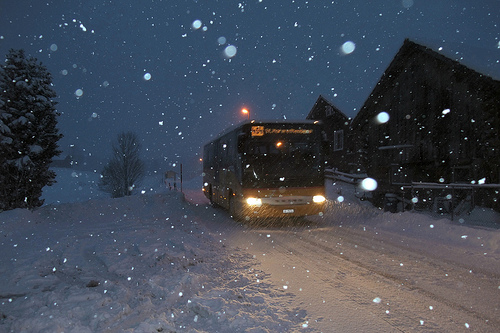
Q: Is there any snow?
A: Yes, there is snow.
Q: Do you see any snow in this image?
A: Yes, there is snow.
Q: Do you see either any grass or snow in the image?
A: Yes, there is snow.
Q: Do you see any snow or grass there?
A: Yes, there is snow.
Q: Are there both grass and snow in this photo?
A: No, there is snow but no grass.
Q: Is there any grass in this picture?
A: No, there is no grass.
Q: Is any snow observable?
A: Yes, there is snow.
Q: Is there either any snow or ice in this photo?
A: Yes, there is snow.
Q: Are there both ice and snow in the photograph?
A: No, there is snow but no ice.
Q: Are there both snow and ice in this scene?
A: No, there is snow but no ice.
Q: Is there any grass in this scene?
A: No, there is no grass.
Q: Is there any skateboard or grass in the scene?
A: No, there are no grass or skateboards.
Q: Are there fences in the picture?
A: No, there are no fences.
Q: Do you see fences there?
A: No, there are no fences.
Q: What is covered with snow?
A: The tree is covered with snow.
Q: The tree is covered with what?
A: The tree is covered with snow.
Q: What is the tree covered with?
A: The tree is covered with snow.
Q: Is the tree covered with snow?
A: Yes, the tree is covered with snow.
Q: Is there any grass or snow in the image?
A: Yes, there is snow.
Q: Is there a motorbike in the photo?
A: No, there are no motorcycles.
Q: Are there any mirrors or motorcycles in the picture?
A: No, there are no motorcycles or mirrors.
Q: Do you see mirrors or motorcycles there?
A: No, there are no motorcycles or mirrors.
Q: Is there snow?
A: Yes, there is snow.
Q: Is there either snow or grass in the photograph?
A: Yes, there is snow.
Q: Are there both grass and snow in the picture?
A: No, there is snow but no grass.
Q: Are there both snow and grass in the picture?
A: No, there is snow but no grass.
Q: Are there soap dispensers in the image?
A: No, there are no soap dispensers.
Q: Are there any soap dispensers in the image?
A: No, there are no soap dispensers.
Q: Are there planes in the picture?
A: No, there are no planes.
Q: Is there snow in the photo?
A: Yes, there is snow.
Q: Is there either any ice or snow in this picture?
A: Yes, there is snow.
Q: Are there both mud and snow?
A: No, there is snow but no mud.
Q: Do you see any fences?
A: No, there are no fences.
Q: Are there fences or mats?
A: No, there are no fences or mats.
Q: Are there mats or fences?
A: No, there are no fences or mats.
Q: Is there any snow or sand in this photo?
A: Yes, there is snow.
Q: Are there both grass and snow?
A: No, there is snow but no grass.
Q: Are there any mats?
A: No, there are no mats.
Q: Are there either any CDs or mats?
A: No, there are no mats or cds.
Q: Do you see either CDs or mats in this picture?
A: No, there are no mats or cds.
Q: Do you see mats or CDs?
A: No, there are no mats or cds.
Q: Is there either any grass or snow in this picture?
A: Yes, there is snow.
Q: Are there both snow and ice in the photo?
A: No, there is snow but no ice.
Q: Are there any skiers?
A: No, there are no skiers.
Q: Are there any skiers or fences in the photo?
A: No, there are no skiers or fences.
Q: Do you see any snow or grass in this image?
A: Yes, there is snow.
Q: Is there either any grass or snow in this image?
A: Yes, there is snow.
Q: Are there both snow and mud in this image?
A: No, there is snow but no mud.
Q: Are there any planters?
A: No, there are no planters.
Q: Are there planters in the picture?
A: No, there are no planters.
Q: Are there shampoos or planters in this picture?
A: No, there are no planters or shampoos.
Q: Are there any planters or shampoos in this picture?
A: No, there are no planters or shampoos.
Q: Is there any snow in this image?
A: Yes, there is snow.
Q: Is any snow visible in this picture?
A: Yes, there is snow.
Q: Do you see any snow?
A: Yes, there is snow.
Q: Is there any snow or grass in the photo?
A: Yes, there is snow.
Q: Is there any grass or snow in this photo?
A: Yes, there is snow.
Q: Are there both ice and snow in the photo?
A: No, there is snow but no ice.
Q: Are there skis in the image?
A: No, there are no skis.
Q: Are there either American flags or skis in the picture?
A: No, there are no skis or American flags.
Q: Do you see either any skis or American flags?
A: No, there are no skis or American flags.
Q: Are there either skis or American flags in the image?
A: No, there are no skis or American flags.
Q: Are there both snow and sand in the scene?
A: No, there is snow but no sand.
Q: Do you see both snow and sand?
A: No, there is snow but no sand.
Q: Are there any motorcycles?
A: No, there are no motorcycles.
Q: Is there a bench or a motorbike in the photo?
A: No, there are no motorcycles or benches.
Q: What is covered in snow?
A: The road is covered in snow.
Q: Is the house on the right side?
A: Yes, the house is on the right of the image.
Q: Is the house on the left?
A: No, the house is on the right of the image.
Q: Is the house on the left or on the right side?
A: The house is on the right of the image.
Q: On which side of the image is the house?
A: The house is on the right of the image.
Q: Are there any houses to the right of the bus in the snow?
A: Yes, there is a house to the right of the bus.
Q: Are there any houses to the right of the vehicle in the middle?
A: Yes, there is a house to the right of the bus.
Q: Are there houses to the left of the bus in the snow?
A: No, the house is to the right of the bus.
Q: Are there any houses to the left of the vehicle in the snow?
A: No, the house is to the right of the bus.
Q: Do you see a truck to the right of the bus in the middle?
A: No, there is a house to the right of the bus.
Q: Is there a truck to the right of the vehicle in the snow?
A: No, there is a house to the right of the bus.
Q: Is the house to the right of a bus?
A: Yes, the house is to the right of a bus.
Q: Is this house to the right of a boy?
A: No, the house is to the right of a bus.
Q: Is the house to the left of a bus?
A: No, the house is to the right of a bus.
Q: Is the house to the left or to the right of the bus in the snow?
A: The house is to the right of the bus.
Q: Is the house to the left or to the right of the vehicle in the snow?
A: The house is to the right of the bus.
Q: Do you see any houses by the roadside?
A: Yes, there is a house by the roadside.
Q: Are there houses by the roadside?
A: Yes, there is a house by the roadside.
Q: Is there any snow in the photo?
A: Yes, there is snow.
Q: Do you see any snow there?
A: Yes, there is snow.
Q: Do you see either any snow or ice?
A: Yes, there is snow.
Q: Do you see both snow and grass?
A: No, there is snow but no grass.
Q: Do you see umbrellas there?
A: No, there are no umbrellas.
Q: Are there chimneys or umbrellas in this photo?
A: No, there are no umbrellas or chimneys.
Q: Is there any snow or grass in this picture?
A: Yes, there is snow.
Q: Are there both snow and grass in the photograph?
A: No, there is snow but no grass.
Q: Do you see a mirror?
A: No, there are no mirrors.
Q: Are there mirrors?
A: No, there are no mirrors.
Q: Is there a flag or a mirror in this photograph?
A: No, there are no mirrors or flags.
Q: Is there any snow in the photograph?
A: Yes, there is snow.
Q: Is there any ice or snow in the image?
A: Yes, there is snow.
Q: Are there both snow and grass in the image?
A: No, there is snow but no grass.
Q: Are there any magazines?
A: No, there are no magazines.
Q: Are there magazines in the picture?
A: No, there are no magazines.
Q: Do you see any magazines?
A: No, there are no magazines.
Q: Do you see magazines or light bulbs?
A: No, there are no magazines or light bulbs.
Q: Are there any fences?
A: No, there are no fences.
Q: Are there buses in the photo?
A: Yes, there is a bus.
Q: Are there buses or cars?
A: Yes, there is a bus.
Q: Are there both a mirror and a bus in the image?
A: No, there is a bus but no mirrors.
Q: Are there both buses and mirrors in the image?
A: No, there is a bus but no mirrors.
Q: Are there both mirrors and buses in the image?
A: No, there is a bus but no mirrors.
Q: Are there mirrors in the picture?
A: No, there are no mirrors.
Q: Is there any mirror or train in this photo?
A: No, there are no mirrors or trains.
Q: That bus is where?
A: The bus is in the snow.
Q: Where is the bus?
A: The bus is in the snow.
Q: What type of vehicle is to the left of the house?
A: The vehicle is a bus.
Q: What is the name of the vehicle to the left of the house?
A: The vehicle is a bus.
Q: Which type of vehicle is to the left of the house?
A: The vehicle is a bus.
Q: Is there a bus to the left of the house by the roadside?
A: Yes, there is a bus to the left of the house.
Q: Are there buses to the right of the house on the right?
A: No, the bus is to the left of the house.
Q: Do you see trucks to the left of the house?
A: No, there is a bus to the left of the house.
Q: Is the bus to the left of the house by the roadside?
A: Yes, the bus is to the left of the house.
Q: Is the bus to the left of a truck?
A: No, the bus is to the left of the house.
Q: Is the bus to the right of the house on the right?
A: No, the bus is to the left of the house.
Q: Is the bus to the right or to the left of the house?
A: The bus is to the left of the house.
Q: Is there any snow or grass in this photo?
A: Yes, there is snow.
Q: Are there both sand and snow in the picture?
A: No, there is snow but no sand.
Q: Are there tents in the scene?
A: No, there are no tents.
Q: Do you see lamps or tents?
A: No, there are no tents or lamps.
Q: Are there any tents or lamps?
A: No, there are no tents or lamps.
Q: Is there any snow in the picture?
A: Yes, there is snow.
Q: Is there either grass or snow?
A: Yes, there is snow.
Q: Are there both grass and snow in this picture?
A: No, there is snow but no grass.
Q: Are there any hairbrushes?
A: No, there are no hairbrushes.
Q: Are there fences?
A: No, there are no fences.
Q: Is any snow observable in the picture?
A: Yes, there is snow.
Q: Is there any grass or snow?
A: Yes, there is snow.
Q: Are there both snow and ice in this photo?
A: No, there is snow but no ice.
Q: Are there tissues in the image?
A: No, there are no tissues.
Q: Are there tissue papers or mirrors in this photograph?
A: No, there are no tissue papers or mirrors.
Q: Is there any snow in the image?
A: Yes, there is snow.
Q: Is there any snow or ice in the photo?
A: Yes, there is snow.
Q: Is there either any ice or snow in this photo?
A: Yes, there is snow.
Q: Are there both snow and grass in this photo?
A: No, there is snow but no grass.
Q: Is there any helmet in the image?
A: No, there are no helmets.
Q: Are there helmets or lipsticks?
A: No, there are no helmets or lipsticks.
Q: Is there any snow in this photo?
A: Yes, there is snow.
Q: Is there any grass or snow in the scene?
A: Yes, there is snow.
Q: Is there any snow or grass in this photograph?
A: Yes, there is snow.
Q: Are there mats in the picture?
A: No, there are no mats.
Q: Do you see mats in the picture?
A: No, there are no mats.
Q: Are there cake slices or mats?
A: No, there are no mats or cake slices.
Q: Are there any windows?
A: Yes, there is a window.